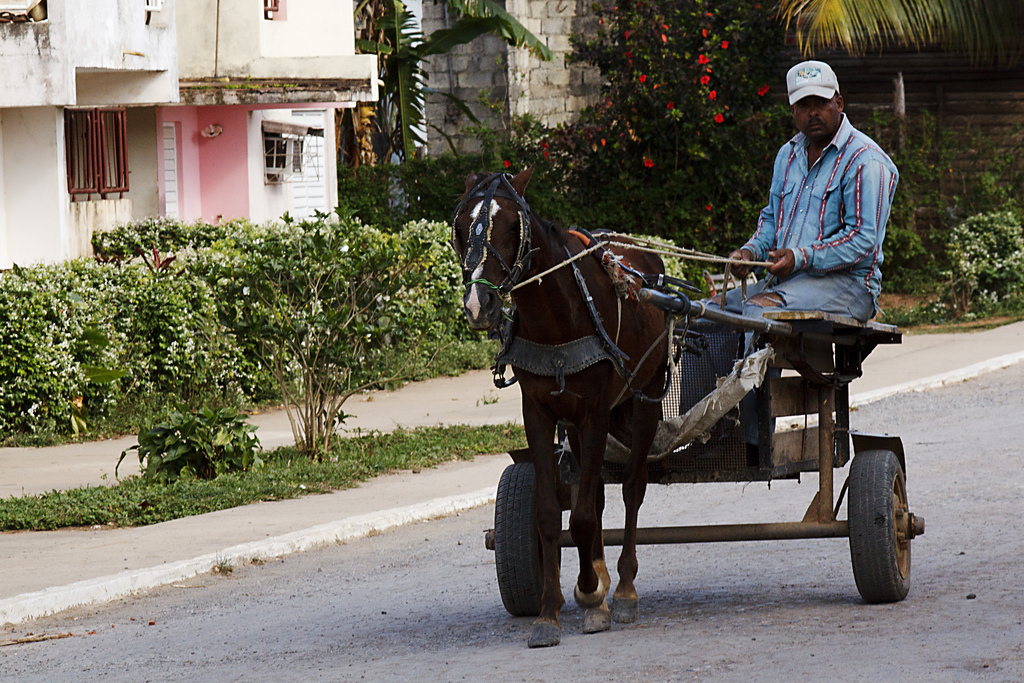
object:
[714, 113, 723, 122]
flowers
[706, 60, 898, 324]
man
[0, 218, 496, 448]
bush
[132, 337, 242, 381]
flowers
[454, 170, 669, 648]
horse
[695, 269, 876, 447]
jeans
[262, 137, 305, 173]
air conditioner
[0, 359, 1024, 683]
concrete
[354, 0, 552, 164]
tree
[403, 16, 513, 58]
leaf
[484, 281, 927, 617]
cart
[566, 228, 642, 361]
reins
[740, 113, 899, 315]
shirt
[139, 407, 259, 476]
trimmed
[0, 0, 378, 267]
building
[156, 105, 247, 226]
entry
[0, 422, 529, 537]
grass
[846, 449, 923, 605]
wheels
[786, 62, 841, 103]
hat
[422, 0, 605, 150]
wall